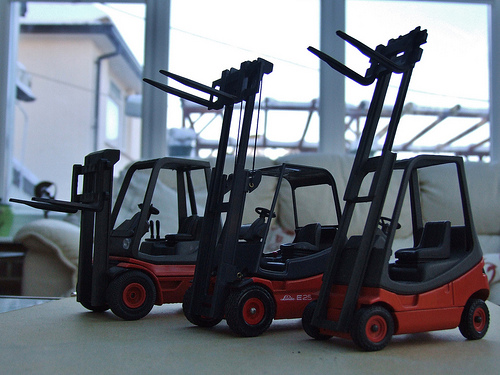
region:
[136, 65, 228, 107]
black levers on fork lift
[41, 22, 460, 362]
three forklifts lined up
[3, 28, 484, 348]
row of three forklifts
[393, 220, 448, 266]
black seat of forklift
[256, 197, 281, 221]
black steering wheel of forklift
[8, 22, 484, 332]
three toy forklifts in a line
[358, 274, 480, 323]
red bottom of fork lift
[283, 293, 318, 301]
white writing on side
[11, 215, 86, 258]
tan arm rest of couch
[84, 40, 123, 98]
storm drain on side of house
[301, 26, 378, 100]
end piece of fork lift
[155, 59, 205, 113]
end piece of fork lift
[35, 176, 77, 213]
end piece of fork lift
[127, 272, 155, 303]
front wheel of lift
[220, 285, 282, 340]
front wheel of lift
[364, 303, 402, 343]
front wheel of lift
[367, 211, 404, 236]
steering wheel in lift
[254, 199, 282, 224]
steering wheel in lift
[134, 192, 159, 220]
steering wheel in lift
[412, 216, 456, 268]
black chair on fork lift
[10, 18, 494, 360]
three fork lifts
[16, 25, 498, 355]
these are miniature fork lifts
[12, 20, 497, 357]
these are toy fork lifts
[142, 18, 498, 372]
these two have fully extended fork lifts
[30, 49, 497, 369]
the models are red and black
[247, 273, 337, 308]
a white decal on the side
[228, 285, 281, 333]
a red wheel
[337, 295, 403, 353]
the tires are black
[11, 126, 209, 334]
this is a red and black fork lift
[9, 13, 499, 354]
three die cast fork lifts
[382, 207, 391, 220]
There is a black steering wheel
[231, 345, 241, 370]
There is a slab of concrete here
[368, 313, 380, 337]
There is a black tire here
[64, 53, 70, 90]
There is an off-cream building here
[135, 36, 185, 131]
There is a tower that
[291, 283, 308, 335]
There is a red vehicle here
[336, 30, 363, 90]
There is a black life here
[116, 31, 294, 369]
Jackson Mingus took this photo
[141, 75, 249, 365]
This photo is very clear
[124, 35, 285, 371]
This photo was taken with a telephoto lens